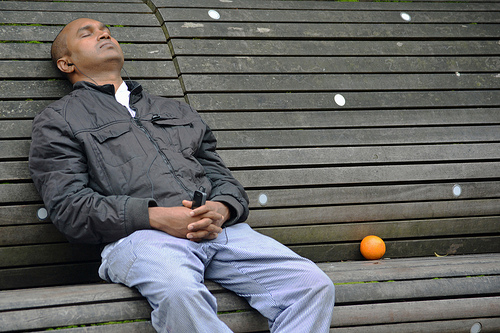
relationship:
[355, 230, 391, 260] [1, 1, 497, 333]
orange on bench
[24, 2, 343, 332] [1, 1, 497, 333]
man on bench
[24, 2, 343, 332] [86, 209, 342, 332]
man wearing jeans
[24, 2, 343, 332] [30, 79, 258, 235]
man wearing jacket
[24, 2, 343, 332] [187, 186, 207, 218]
man clasping phone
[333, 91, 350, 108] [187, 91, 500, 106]
dot on slat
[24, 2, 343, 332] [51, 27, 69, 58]
man with hair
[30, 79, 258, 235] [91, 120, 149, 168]
jacket has pocket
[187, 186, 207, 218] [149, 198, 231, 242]
phone in hands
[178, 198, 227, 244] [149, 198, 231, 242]
fingers of hands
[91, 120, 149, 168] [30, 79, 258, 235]
pocket on jacket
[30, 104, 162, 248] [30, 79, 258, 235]
sleeve of jacket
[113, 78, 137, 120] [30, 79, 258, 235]
shirt under jacket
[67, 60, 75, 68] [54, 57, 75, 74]
earbud in ear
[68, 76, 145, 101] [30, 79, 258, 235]
collar on coat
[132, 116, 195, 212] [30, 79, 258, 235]
zipper on jacket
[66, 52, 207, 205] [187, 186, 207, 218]
wire from phone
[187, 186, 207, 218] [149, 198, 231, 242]
mp3 player between hands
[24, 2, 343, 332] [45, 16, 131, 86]
man has skin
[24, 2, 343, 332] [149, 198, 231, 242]
man has skin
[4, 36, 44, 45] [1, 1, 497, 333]
moss in bench